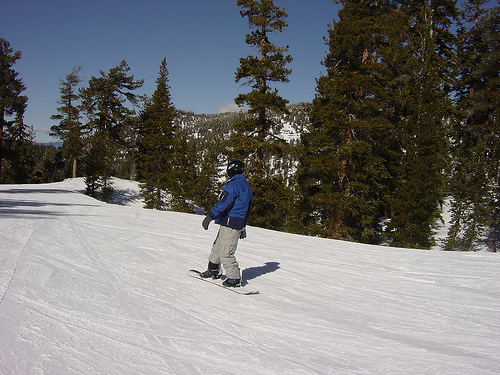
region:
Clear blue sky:
[54, 9, 213, 44]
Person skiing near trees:
[190, 49, 329, 282]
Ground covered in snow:
[1, 212, 191, 312]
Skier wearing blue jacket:
[184, 155, 271, 295]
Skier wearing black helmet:
[205, 154, 257, 294]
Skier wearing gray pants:
[189, 153, 251, 288]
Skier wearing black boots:
[201, 153, 252, 290]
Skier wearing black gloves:
[185, 154, 265, 298]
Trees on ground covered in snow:
[54, 50, 196, 221]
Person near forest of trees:
[139, 43, 497, 270]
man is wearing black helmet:
[220, 154, 255, 176]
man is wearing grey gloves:
[196, 199, 259, 249]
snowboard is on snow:
[186, 265, 256, 300]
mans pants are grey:
[210, 212, 250, 284]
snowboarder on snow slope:
[175, 147, 287, 301]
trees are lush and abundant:
[100, 69, 326, 234]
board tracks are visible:
[48, 192, 166, 367]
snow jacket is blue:
[201, 173, 269, 238]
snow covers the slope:
[17, 182, 449, 368]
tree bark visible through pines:
[317, 97, 372, 257]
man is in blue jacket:
[197, 148, 276, 231]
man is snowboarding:
[167, 135, 269, 315]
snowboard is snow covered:
[178, 265, 268, 306]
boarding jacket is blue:
[188, 150, 270, 245]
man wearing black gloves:
[199, 197, 217, 241]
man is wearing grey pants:
[201, 222, 249, 284]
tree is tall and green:
[231, 10, 291, 252]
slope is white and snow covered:
[12, 185, 494, 368]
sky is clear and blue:
[21, 3, 328, 129]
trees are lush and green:
[301, 15, 498, 261]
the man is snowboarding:
[188, 162, 258, 294]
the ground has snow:
[0, 177, 499, 374]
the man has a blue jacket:
[202, 174, 247, 229]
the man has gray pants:
[207, 225, 242, 278]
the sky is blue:
[1, 0, 498, 146]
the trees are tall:
[0, 0, 498, 251]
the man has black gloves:
[201, 215, 246, 237]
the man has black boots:
[202, 266, 243, 286]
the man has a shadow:
[243, 260, 277, 280]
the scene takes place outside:
[1, 0, 497, 374]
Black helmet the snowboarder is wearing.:
[223, 159, 244, 174]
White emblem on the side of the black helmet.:
[225, 161, 237, 170]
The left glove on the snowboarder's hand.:
[203, 211, 211, 231]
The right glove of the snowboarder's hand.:
[238, 225, 249, 237]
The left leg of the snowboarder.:
[210, 231, 217, 259]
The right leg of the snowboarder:
[220, 226, 240, 277]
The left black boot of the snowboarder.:
[204, 258, 222, 279]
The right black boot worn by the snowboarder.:
[223, 274, 240, 285]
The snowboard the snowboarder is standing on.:
[186, 260, 261, 299]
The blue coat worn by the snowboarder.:
[211, 171, 252, 233]